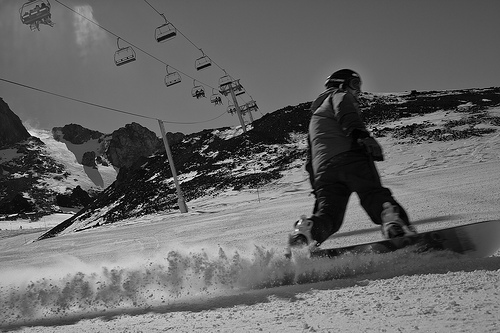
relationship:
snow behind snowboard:
[2, 236, 455, 324] [286, 229, 474, 253]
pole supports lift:
[159, 119, 190, 214] [2, 1, 265, 212]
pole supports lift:
[226, 80, 248, 134] [2, 1, 265, 212]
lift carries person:
[2, 1, 265, 212] [40, 2, 56, 28]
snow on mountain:
[2, 86, 499, 295] [1, 93, 189, 222]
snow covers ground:
[2, 86, 499, 295] [3, 170, 496, 332]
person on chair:
[199, 89, 205, 99] [190, 79, 208, 99]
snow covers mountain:
[2, 86, 499, 295] [1, 85, 495, 241]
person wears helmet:
[289, 68, 418, 247] [326, 68, 361, 92]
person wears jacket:
[289, 68, 418, 247] [305, 89, 370, 175]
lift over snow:
[2, 1, 265, 212] [2, 86, 499, 295]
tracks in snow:
[401, 133, 496, 173] [2, 86, 499, 295]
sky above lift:
[2, 1, 500, 132] [2, 1, 265, 212]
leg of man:
[307, 160, 350, 245] [289, 68, 418, 247]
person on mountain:
[289, 68, 418, 247] [1, 85, 495, 241]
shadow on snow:
[315, 213, 458, 239] [2, 86, 499, 295]